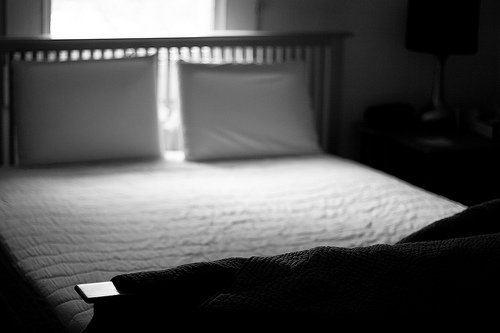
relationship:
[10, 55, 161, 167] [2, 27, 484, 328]
pillow are on bed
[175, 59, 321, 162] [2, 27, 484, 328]
pillow are on bed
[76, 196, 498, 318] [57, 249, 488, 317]
blanket over footboard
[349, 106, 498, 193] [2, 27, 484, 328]
table beside bed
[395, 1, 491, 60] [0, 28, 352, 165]
shade on headboard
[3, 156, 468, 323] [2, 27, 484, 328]
sheet are on bed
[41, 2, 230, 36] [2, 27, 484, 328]
window behind bed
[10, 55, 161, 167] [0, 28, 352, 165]
pillow leaning on headboard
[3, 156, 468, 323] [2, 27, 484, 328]
sheet on bed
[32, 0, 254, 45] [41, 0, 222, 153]
light streaming through window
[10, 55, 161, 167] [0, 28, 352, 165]
pillow are on headboard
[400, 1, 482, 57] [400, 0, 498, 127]
shade of lamp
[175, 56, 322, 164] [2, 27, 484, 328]
pillow on bed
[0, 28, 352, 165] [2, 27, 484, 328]
headboard on bed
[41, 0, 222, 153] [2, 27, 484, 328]
window behind bed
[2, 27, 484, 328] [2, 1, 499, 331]
bed in room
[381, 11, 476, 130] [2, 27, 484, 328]
lamp near bed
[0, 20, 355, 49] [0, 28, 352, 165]
slat on headboard